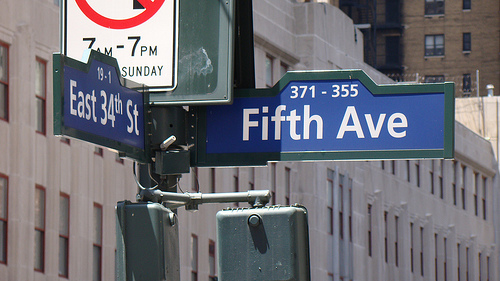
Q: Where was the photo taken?
A: In a big city - perhaps NYC.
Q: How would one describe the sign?
A: This is a a blue and white street name sign.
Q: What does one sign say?
A: Fifth Ave.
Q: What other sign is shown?
A: A no turn sign.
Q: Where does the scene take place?
A: Near a city street.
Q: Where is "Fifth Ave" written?
A: On right blue sign.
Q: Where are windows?
A: On the buildings.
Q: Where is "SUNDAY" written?
A: On white sign.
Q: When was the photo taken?
A: During the daytime.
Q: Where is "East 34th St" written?
A: On left blue sign.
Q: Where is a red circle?
A: On white sign.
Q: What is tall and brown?
A: Building.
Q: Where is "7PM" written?
A: On the white sign.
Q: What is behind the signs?
A: Buildings.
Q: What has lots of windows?
A: A building.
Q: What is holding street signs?
A: A pole.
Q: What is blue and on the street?
A: A sign.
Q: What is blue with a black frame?
A: A sign.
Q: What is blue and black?
A: A sign.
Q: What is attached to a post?
A: A street sign.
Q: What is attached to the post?
A: A street sign.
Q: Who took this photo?
A: A tourist.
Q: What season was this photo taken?
A: Spring.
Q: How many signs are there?
A: Two.